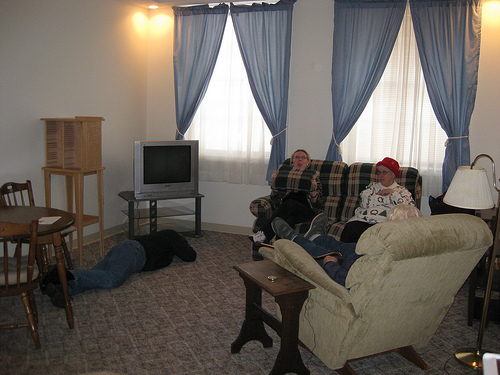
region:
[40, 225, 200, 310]
A person lying on the floor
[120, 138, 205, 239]
A TV on a stand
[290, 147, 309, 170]
A woman sticking her tongue out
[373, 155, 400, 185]
A woman win a red hat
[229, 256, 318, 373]
A brown side table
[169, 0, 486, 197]
Blue curtains on the windows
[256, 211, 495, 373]
A tan colored recliner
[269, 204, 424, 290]
A person in a recliner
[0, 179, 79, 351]
A table and two chairs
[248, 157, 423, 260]
A plaid colored couch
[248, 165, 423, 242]
green plaid couch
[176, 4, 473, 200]
two windows with blue curtains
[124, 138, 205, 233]
television on a TV stand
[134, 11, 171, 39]
light in the corner above TV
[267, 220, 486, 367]
beige recliner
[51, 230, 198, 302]
person in blue jeans and black shirt on floor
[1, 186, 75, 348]
a wood table and chairs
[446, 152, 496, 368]
floor lamp behind the recliner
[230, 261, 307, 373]
table beside the recliner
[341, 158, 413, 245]
woman in a red hat on the couch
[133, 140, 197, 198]
grey flat screen tv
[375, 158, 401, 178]
red hat on head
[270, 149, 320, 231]
woman sitting on sofa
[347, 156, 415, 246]
woman wearing white sweater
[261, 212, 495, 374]
tan plush recliner chair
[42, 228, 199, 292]
person laying on floor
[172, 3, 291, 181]
blue curtains on window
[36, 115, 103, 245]
tan wood cabinet in living room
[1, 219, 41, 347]
brown wood dining chair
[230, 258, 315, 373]
brown wood table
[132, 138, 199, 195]
a silver TV set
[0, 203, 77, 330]
a dark wood table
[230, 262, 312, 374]
a small side table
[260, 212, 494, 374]
a tan rocking chair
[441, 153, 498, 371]
a floor lamp with shade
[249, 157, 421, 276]
a green striped couch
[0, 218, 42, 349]
a brown kitchen chair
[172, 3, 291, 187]
a set of blue curtain panes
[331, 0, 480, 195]
a set of blue curtain panes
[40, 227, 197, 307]
a person laying on floor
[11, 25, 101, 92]
wall is white color.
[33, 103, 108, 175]
Box is brown color.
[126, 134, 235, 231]
TV screen is off.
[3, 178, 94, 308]
Table is brown color.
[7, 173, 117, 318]
table is made of wood.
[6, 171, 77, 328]
Two chairs are around the table.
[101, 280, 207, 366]
Floor is grey color.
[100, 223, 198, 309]
One man is lying in floor.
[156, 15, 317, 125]
Window curtain is blue color.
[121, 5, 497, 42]
Lights are on.